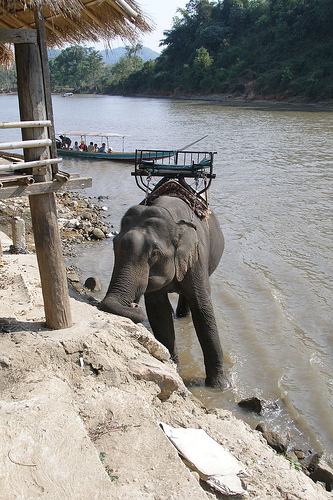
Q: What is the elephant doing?
A: Resting.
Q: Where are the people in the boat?
A: Behind the elephant.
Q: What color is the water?
A: Brown.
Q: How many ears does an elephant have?
A: Two.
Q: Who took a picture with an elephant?
A: No one.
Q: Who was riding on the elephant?
A: No one.